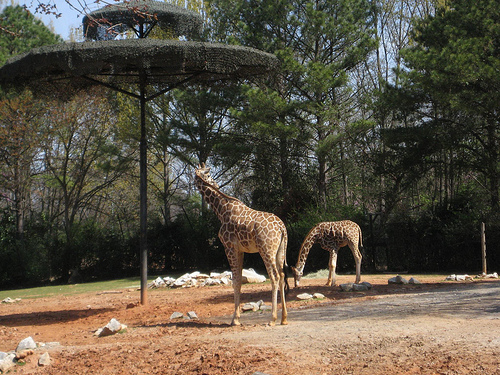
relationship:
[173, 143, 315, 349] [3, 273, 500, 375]
giraffe on ground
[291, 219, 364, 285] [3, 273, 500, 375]
giraffe on ground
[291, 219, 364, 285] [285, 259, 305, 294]
giraffe has head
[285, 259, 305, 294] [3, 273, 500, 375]
head touching ground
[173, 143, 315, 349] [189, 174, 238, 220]
giraffe has neck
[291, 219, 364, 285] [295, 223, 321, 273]
giraffe has neck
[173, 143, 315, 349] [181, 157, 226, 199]
giraffe has head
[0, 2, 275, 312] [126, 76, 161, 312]
umbrella has pole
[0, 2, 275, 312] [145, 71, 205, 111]
umbrella has support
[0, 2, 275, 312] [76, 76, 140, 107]
umbrella has support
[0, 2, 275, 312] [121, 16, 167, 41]
umbrella has support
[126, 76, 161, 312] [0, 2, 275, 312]
pole under umbrella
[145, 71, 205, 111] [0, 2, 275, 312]
support under umbrella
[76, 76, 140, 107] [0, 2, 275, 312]
support under umbrella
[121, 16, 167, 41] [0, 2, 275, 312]
support under umbrella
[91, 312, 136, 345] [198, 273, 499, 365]
stones near path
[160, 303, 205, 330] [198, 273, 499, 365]
stones near path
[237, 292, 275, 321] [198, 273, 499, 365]
stones near path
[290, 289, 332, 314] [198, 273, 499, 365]
stones near path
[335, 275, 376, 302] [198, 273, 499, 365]
stones near path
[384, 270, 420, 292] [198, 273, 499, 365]
stones near path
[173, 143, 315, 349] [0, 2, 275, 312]
giraffe under umbrella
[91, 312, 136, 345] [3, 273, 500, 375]
stones on ground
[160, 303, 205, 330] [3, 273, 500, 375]
stones on ground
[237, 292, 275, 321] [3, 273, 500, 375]
stones on ground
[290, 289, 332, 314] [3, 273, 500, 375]
stones on ground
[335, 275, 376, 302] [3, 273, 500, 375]
stones on ground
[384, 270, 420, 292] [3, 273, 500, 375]
stones on ground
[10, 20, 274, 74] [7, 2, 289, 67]
structure has tiers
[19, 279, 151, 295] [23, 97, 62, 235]
grass in front of tree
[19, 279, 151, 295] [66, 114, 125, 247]
grass in front of tree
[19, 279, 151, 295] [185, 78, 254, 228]
grass in front of tree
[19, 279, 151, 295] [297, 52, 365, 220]
grass in front of tree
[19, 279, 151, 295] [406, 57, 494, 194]
grass in front of tree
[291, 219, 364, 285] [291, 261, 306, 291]
giraffe has head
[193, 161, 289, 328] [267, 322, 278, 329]
giraffe has hoof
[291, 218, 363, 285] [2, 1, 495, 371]
giraffe in photo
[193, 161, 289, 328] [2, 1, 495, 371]
giraffe in photo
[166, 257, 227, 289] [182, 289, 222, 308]
rocks on ground